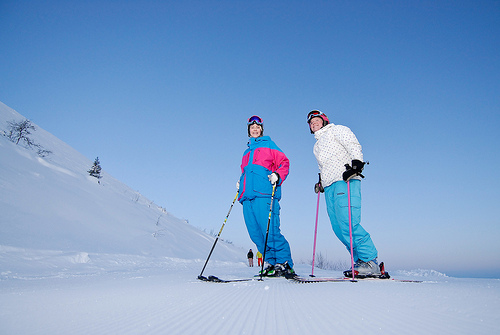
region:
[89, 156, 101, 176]
evergreen tree on the hillside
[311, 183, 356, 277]
pink ski poles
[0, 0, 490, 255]
clear blue skies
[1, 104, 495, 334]
ground is covered in snow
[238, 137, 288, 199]
blue ski jacket with a pink stripe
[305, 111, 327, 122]
ski goggles on the woman's head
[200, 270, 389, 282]
two sets of snow skies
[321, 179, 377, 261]
blue snow pants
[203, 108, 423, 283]
two women in the ski clothes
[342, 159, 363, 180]
black snow gloves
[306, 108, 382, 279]
A female skier in a white coat and blue pants.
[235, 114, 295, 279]
A female skier in pink and blue.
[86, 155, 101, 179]
A pine tree on the side of a hill.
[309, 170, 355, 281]
Pink ski poles in a woman's hands.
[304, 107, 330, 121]
White and pink goggles on a woman's face.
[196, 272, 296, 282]
Black skis on a woman to the left of another woman.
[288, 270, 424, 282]
Long skis on the feet of a woman to the right of another woman.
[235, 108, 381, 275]
Two skiiing women with goggles on their heads.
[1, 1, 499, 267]
All the blue sky.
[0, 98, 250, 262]
A sloped snowy hill with two trees growing.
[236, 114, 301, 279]
skier dressed in pink and blue clothing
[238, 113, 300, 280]
female skier on snow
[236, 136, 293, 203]
blue and pink coat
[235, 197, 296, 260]
blue pants on a skier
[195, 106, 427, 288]
two female skiers standing next to each other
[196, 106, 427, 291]
two female skiers on snow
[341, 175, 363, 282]
fucshia colored ski pole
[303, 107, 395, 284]
female skier holding two ski poles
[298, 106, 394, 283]
woman on a skis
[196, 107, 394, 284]
skiers on snow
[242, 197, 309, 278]
woman wearing blue ski pants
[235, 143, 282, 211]
woman wearing blue and red ski jacket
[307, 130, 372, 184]
woman wearing a white jacket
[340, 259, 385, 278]
woman wearing gray ski boots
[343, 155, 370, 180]
woman wearing black gloves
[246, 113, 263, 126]
woman wearing ski glasses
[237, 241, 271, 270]
man standing in the snow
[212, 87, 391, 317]
two woman on skis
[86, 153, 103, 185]
tree on a mountain top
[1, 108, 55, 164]
bushes in the snow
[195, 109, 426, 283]
two women on the ski slope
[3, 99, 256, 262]
snow-covered mountain on the left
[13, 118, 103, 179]
two small trees on the side of the mountain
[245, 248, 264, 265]
two people in the distance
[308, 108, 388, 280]
woman in a white jacket and blue pants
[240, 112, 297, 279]
woman in the blue and pink jacket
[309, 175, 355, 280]
pink ski poles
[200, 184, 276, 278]
black and white ski poles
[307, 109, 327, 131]
white goggles with a red band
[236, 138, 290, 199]
a blue and pink ski jacket